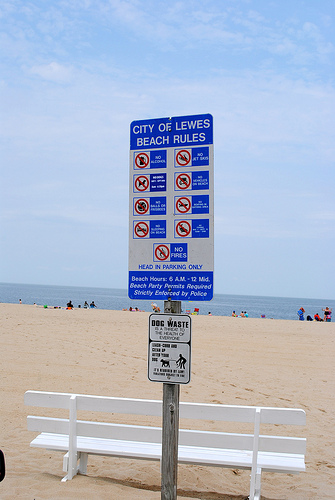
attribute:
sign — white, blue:
[122, 106, 225, 304]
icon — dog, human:
[160, 347, 189, 368]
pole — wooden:
[158, 299, 185, 498]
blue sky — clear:
[2, 2, 334, 104]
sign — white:
[141, 308, 191, 386]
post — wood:
[103, 108, 236, 292]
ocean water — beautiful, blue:
[0, 282, 334, 318]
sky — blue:
[1, 0, 333, 300]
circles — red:
[122, 142, 222, 273]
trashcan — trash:
[0, 445, 7, 481]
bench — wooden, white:
[15, 388, 316, 493]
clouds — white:
[27, 25, 38, 39]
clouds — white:
[22, 60, 73, 84]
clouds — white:
[262, 38, 295, 57]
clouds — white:
[191, 9, 217, 22]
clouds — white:
[300, 20, 325, 46]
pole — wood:
[156, 302, 184, 498]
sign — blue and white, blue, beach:
[128, 114, 213, 303]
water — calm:
[0, 281, 334, 319]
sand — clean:
[0, 301, 333, 498]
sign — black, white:
[151, 315, 200, 330]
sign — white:
[128, 313, 202, 373]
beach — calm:
[3, 283, 90, 294]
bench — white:
[10, 368, 283, 498]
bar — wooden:
[157, 377, 218, 482]